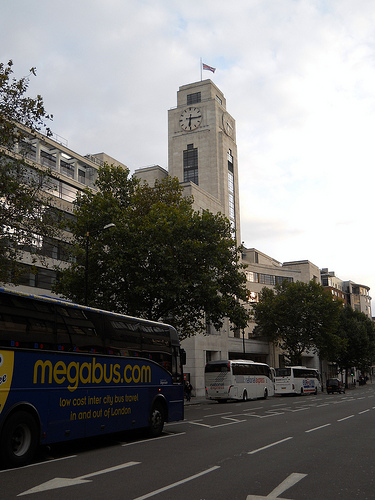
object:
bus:
[0, 286, 189, 465]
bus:
[203, 357, 277, 403]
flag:
[202, 63, 216, 74]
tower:
[166, 78, 244, 203]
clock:
[178, 105, 203, 134]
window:
[71, 325, 90, 354]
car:
[324, 377, 345, 395]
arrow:
[15, 458, 141, 498]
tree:
[55, 162, 253, 339]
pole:
[199, 59, 202, 81]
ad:
[32, 358, 152, 394]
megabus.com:
[32, 358, 154, 394]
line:
[247, 433, 295, 456]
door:
[165, 350, 184, 418]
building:
[166, 77, 242, 404]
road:
[2, 441, 374, 498]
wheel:
[146, 408, 165, 438]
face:
[184, 114, 198, 128]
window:
[187, 166, 196, 181]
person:
[183, 379, 193, 403]